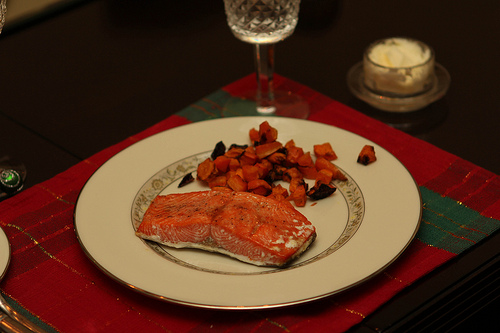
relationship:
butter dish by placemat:
[359, 32, 436, 98] [2, 69, 493, 324]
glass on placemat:
[224, 7, 306, 118] [256, 65, 471, 236]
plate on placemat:
[72, 115, 424, 309] [2, 69, 493, 324]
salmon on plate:
[136, 189, 316, 271] [72, 115, 424, 309]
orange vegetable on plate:
[313, 140, 337, 159] [88, 241, 293, 308]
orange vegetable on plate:
[292, 185, 307, 207] [88, 241, 293, 308]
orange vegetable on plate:
[299, 151, 313, 166] [88, 241, 293, 308]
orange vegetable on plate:
[196, 158, 211, 178] [88, 241, 293, 308]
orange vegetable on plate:
[227, 173, 244, 190] [88, 241, 293, 308]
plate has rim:
[72, 115, 424, 309] [72, 114, 422, 310]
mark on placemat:
[1, 170, 21, 189] [2, 69, 493, 324]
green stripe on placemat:
[209, 96, 479, 252] [2, 69, 493, 324]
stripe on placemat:
[1, 221, 146, 316] [2, 69, 493, 324]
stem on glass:
[251, 41, 276, 112] [220, 0, 310, 121]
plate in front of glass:
[72, 115, 424, 309] [220, 0, 310, 121]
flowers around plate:
[173, 153, 368, 279] [72, 115, 424, 309]